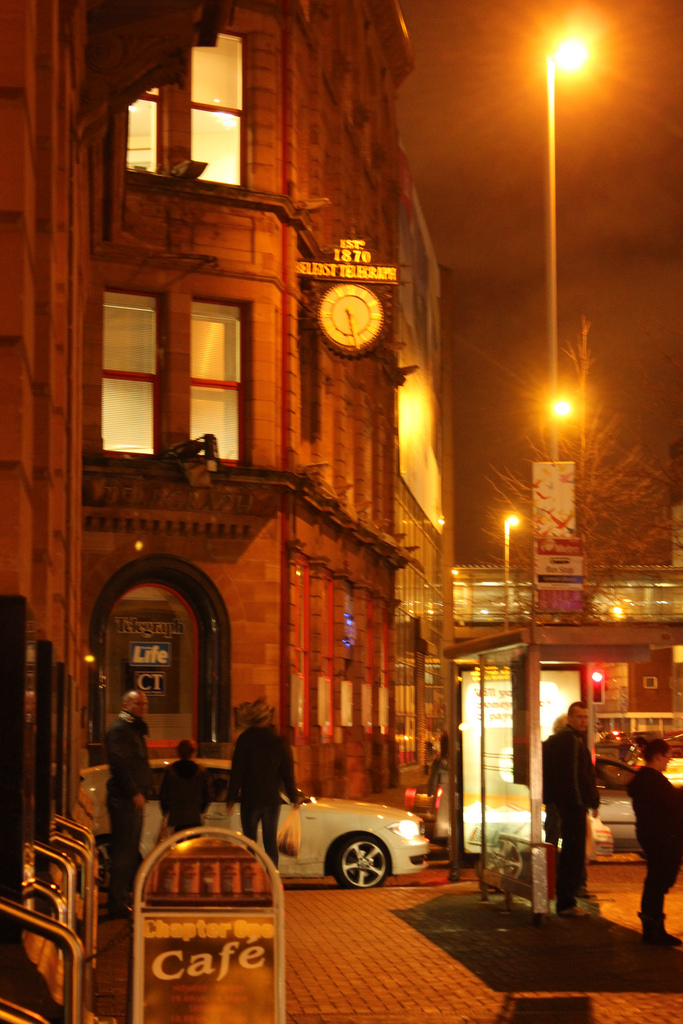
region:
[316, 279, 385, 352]
A white round clock.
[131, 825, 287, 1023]
Rounded white sign that says Cafe on it.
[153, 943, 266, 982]
White word Cafe.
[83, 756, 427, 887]
A white car with lights on.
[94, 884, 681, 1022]
A tan brick walkway.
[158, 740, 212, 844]
Brown haired boy beside a white car.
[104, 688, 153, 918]
Man with little hair in a black coat next to a white car looking back.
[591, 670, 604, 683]
A red light on a traffic light.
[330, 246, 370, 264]
Gold 1870 above a clock.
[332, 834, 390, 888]
A front passenger wheel on a white car.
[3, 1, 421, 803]
white clock on brown building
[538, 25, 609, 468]
street light on metal pole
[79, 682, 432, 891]
bald man standing next to white car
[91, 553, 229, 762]
blue 'Life" sign in arched window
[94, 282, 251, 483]
red trim around the window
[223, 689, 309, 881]
man is wearing a cowboy hat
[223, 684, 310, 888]
man is holding a plastic bag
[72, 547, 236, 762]
black trim around arched window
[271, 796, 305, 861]
Man carrying a bag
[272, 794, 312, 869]
Man is carrying a bag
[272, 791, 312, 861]
Man carrying a plastic bag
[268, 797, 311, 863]
Man is carrying a plastic bag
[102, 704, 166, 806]
Man wearing a jacket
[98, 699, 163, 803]
Man is wearing a jacket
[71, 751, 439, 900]
Car is stopped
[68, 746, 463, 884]
White car is stopped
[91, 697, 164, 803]
Man wearing a black jacket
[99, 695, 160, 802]
Man is wearing a black jacket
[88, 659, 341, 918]
a group of people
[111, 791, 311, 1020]
sign on the sidewalk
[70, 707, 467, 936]
car on the street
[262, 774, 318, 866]
man holding a bag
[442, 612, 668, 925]
a lit bus stop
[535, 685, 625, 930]
man standing at bus stop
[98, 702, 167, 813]
man wearing a jacket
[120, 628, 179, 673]
a blue and white sign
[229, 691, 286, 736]
man wearing a hat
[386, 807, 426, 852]
headlight on the car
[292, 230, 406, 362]
A clock on a building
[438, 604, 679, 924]
A bus stop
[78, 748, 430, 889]
A white car on the street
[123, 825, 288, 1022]
a metal cafe sign on a sidewalk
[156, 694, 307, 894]
two people next to a white car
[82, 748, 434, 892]
white car on the street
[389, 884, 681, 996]
large dark shadow on the sidewalk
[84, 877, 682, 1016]
red brick city sidewalk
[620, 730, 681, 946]
woman standing along the road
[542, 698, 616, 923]
man holding a white bag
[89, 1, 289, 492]
four windows on a brick building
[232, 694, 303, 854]
man wearing a hat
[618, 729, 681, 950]
woman with a ponytail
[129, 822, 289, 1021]
business sign on the sidewalk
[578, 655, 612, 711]
traffic light on the street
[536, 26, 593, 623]
street light on the sidewalk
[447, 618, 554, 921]
bus stop enclosure on the street curb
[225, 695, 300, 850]
man in a black jacket and plastic bag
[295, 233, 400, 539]
clock on the side of a building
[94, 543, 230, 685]
arched window with advertising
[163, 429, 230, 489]
camera mounted on a building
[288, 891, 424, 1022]
brick pavers on the walkway